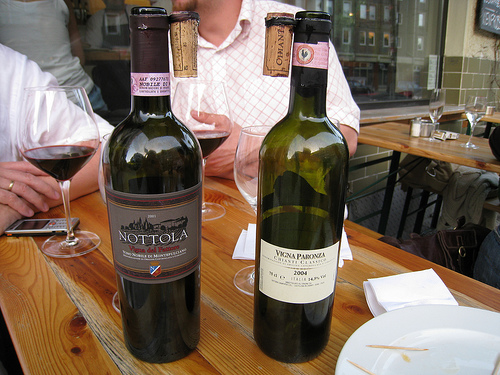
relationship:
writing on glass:
[109, 225, 200, 268] [13, 88, 112, 310]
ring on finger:
[6, 180, 20, 190] [0, 171, 60, 221]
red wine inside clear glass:
[18, 146, 99, 180] [16, 83, 101, 258]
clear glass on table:
[16, 83, 101, 258] [19, 83, 497, 373]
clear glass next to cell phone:
[16, 83, 101, 258] [4, 216, 81, 236]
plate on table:
[319, 285, 498, 372] [1, 172, 496, 373]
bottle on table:
[250, 7, 354, 372] [1, 172, 496, 373]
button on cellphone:
[47, 211, 61, 236] [5, 212, 82, 238]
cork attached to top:
[249, 5, 299, 88] [280, 0, 342, 38]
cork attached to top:
[168, 5, 208, 77] [119, 5, 167, 37]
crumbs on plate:
[392, 348, 422, 367] [324, 298, 499, 373]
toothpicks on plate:
[348, 339, 438, 373] [334, 307, 499, 373]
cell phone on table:
[1, 206, 81, 240] [7, 154, 468, 374]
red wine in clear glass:
[18, 147, 99, 180] [16, 83, 101, 258]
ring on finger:
[7, 175, 19, 189] [1, 42, 111, 235]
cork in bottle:
[262, 11, 298, 78] [250, 7, 354, 372]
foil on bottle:
[122, 5, 171, 106] [148, 2, 352, 327]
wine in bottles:
[102, 14, 204, 361] [102, 12, 349, 367]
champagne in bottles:
[253, 8, 351, 363] [102, 12, 349, 367]